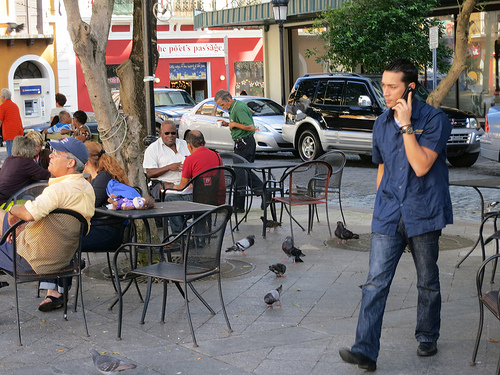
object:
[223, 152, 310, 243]
table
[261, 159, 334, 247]
chair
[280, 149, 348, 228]
chair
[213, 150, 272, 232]
chair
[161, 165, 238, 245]
chair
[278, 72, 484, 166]
car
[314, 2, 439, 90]
tree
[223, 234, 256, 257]
pigeons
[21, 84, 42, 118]
atm machine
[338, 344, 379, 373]
shoes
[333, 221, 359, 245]
pigeon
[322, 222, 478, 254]
manhole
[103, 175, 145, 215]
trunk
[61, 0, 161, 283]
tree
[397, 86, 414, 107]
phone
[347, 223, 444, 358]
jeans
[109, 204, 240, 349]
chair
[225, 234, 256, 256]
bird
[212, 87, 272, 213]
man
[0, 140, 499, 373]
ground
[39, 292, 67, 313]
flip flop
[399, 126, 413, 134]
watch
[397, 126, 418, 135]
wrist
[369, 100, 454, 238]
navy shirt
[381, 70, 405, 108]
face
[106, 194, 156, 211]
doll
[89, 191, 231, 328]
table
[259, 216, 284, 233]
pigeons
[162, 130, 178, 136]
sunglasses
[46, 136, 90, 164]
cap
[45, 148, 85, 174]
head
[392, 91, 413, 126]
hand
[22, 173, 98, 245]
yellow shirt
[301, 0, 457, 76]
branches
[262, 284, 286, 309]
bird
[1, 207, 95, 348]
chair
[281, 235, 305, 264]
pigeons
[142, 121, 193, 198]
man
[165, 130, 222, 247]
man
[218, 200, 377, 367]
sidewalk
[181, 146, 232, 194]
shirt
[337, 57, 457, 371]
he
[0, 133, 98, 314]
he